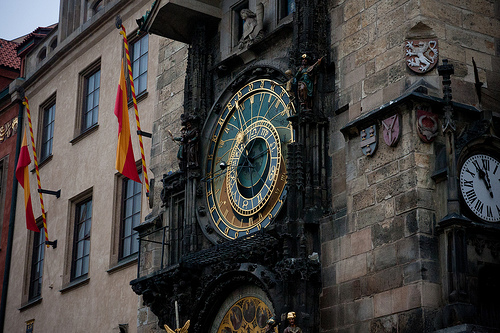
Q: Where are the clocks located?
A: On the sides of the building.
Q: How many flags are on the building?
A: Two.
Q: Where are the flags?
A: Attached to the wall.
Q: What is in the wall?
A: Windows.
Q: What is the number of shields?
A: Four.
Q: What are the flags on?
A: Poles.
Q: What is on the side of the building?
A: Windows.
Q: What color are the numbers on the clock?
A: Gold.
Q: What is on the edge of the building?
A: Plaques.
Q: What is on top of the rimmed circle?
A: Ring.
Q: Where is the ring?
A: Off center.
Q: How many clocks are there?
A: Two.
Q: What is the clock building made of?
A: Brick.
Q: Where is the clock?
A: On the building.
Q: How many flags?
A: 2.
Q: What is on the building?
A: Clocks.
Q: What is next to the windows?
A: Flags.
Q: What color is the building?
A: Brown.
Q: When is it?
A: 11:00am.